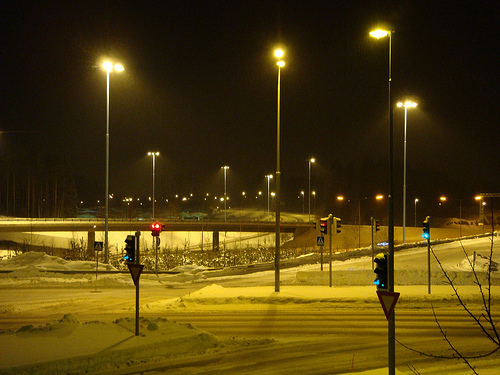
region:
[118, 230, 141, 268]
A traffic light in the "go" position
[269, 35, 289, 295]
A tall, thin, illuminated streetlight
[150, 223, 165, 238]
A traffic light in the "stop" position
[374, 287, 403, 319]
A red and white triangular yield sign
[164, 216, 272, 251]
An elevated freeway overpass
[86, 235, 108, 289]
A small black and white street sign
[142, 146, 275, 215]
Three streetlights side by side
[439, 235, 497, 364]
Barren leafless branches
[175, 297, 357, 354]
A snowplowed road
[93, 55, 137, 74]
A brightly lit pair of lights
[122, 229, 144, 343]
Traffice light on the side of the street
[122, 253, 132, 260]
Green light of the traffic light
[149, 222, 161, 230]
Red light of the traffice light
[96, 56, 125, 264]
Tall street light lamp near the road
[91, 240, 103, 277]
Street sign on the side of the street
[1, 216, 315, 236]
Road bridge in the background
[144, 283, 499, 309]
Street covered in snow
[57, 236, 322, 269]
Dry plants on the side of the street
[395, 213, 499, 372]
Twig branches near the traffic light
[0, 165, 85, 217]
Tall tree trunks in the background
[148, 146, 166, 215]
light pole in the ground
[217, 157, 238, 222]
light pole in the ground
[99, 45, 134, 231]
light pole in the ground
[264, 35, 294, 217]
light pole in the ground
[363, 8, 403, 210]
light pole in the ground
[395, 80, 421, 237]
light pole in the ground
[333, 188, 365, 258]
light pole in the ground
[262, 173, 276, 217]
light pole in the ground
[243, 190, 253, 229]
light pole in the ground